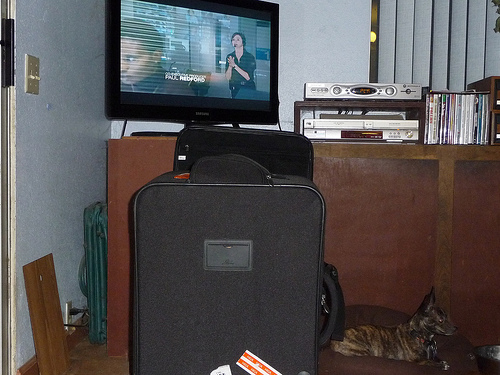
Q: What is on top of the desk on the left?
A: Tv.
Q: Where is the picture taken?
A: In a room.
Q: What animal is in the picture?
A: A dog.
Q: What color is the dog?
A: Brown.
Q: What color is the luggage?
A: Black.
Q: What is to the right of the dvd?
A: Movies.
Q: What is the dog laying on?
A: A dog bed.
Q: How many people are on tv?
A: 2.